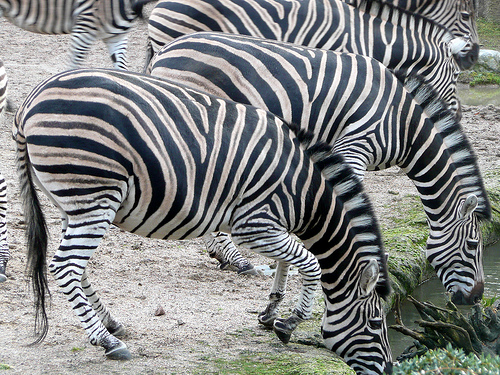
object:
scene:
[0, 3, 491, 374]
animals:
[2, 2, 498, 374]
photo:
[0, 3, 500, 374]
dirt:
[0, 0, 312, 373]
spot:
[382, 203, 498, 359]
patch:
[392, 338, 497, 374]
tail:
[9, 117, 54, 346]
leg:
[45, 171, 137, 347]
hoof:
[105, 343, 130, 361]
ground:
[0, 16, 497, 374]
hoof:
[274, 320, 295, 343]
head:
[319, 262, 395, 373]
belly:
[113, 174, 237, 241]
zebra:
[11, 68, 391, 372]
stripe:
[48, 103, 230, 226]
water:
[369, 206, 499, 373]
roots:
[386, 291, 499, 359]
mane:
[274, 122, 393, 298]